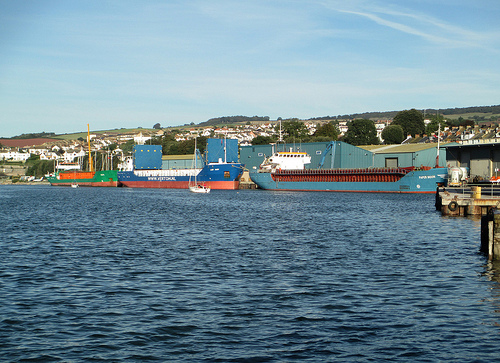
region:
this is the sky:
[17, 5, 322, 56]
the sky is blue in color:
[6, 4, 34, 37]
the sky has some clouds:
[93, 72, 333, 109]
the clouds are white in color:
[156, 83, 336, 114]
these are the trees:
[350, 108, 422, 138]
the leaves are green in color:
[354, 121, 369, 141]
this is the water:
[101, 225, 423, 347]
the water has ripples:
[181, 236, 340, 322]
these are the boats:
[45, 137, 456, 187]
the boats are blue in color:
[331, 147, 359, 167]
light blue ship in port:
[241, 136, 464, 197]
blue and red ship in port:
[112, 155, 243, 190]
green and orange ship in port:
[38, 156, 121, 189]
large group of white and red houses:
[1, 131, 124, 168]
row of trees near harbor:
[24, 104, 474, 184]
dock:
[433, 174, 498, 220]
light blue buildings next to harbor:
[230, 137, 455, 177]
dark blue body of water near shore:
[1, 181, 497, 361]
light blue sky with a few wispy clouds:
[1, 0, 498, 141]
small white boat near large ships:
[183, 131, 213, 196]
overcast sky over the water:
[14, 10, 494, 100]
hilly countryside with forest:
[25, 93, 498, 140]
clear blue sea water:
[8, 193, 443, 352]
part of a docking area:
[433, 154, 498, 306]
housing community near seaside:
[5, 119, 495, 162]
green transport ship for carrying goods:
[40, 145, 120, 195]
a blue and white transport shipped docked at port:
[251, 142, 460, 209]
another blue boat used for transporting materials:
[250, 142, 451, 207]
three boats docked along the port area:
[35, 120, 495, 200]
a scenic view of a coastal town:
[6, 105, 497, 200]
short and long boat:
[248, 160, 447, 202]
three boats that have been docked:
[38, 156, 451, 198]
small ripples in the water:
[277, 296, 372, 345]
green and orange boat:
[48, 167, 121, 189]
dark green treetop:
[343, 118, 375, 143]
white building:
[2, 148, 30, 163]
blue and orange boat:
[115, 168, 247, 189]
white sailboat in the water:
[181, 138, 211, 198]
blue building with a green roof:
[370, 138, 440, 171]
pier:
[432, 180, 494, 217]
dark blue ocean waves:
[85, 259, 385, 342]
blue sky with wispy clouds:
[307, 8, 438, 74]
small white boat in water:
[189, 178, 219, 199]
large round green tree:
[378, 122, 405, 141]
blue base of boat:
[259, 177, 441, 194]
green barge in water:
[41, 172, 117, 184]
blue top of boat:
[128, 165, 238, 180]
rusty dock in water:
[423, 179, 493, 214]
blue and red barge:
[248, 161, 432, 189]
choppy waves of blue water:
[238, 296, 327, 327]